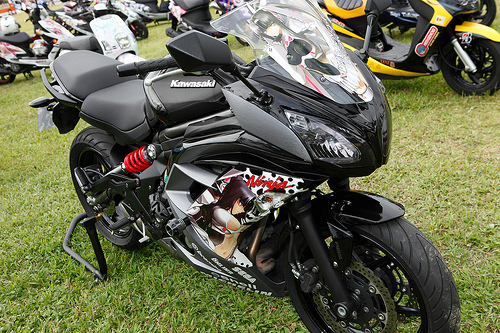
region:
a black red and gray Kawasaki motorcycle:
[38, 4, 461, 331]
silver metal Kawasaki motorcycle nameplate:
[168, 76, 221, 90]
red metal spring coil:
[125, 145, 150, 171]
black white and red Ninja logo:
[213, 163, 298, 200]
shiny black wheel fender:
[311, 186, 401, 226]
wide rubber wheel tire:
[281, 194, 458, 328]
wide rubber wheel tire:
[69, 121, 151, 249]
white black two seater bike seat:
[44, 37, 158, 129]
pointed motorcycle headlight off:
[280, 102, 354, 162]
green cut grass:
[4, 16, 499, 330]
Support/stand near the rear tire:
[55, 211, 110, 286]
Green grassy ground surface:
[16, 286, 218, 325]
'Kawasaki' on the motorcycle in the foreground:
[165, 74, 221, 91]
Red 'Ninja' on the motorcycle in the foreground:
[243, 170, 293, 192]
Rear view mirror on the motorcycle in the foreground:
[162, 27, 241, 76]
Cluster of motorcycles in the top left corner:
[5, 8, 87, 54]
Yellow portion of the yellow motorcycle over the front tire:
[454, 17, 496, 42]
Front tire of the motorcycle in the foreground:
[396, 229, 440, 273]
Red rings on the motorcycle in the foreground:
[117, 146, 155, 175]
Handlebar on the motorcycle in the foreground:
[110, 61, 182, 78]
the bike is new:
[44, 0, 463, 330]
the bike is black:
[52, 0, 466, 330]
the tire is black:
[281, 205, 461, 330]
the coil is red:
[120, 145, 152, 177]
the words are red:
[246, 171, 293, 192]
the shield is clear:
[211, 1, 374, 110]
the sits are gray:
[46, 47, 145, 147]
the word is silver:
[160, 76, 221, 93]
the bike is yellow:
[329, 0, 495, 101]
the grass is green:
[0, 269, 281, 329]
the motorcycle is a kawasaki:
[163, 70, 225, 92]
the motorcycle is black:
[29, 0, 469, 331]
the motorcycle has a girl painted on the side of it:
[197, 175, 257, 259]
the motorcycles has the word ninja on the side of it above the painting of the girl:
[242, 172, 296, 190]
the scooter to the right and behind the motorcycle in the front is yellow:
[317, 0, 494, 95]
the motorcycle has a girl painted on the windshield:
[241, 9, 381, 113]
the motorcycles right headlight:
[280, 105, 366, 190]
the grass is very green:
[0, 5, 499, 330]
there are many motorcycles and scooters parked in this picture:
[1, 0, 493, 330]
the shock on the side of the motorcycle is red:
[119, 145, 151, 176]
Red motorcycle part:
[104, 133, 188, 196]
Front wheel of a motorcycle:
[220, 152, 455, 331]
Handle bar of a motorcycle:
[85, 48, 338, 128]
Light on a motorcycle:
[258, 83, 388, 213]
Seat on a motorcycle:
[35, 25, 160, 122]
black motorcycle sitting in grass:
[13, 7, 498, 306]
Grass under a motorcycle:
[333, 73, 499, 110]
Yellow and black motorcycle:
[295, 0, 490, 100]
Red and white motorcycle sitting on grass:
[5, 27, 139, 97]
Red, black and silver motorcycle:
[27, 9, 462, 321]